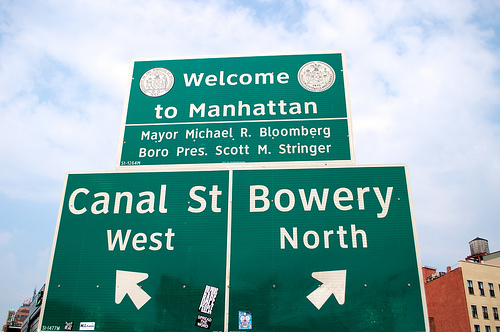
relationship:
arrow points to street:
[96, 262, 162, 314] [180, 170, 230, 219]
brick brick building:
[425, 265, 470, 331] [417, 233, 497, 330]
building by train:
[417, 233, 497, 330] [19, 285, 48, 331]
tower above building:
[457, 233, 495, 260] [417, 233, 497, 330]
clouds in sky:
[15, 24, 131, 84] [0, 2, 500, 271]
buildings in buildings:
[3, 280, 43, 331] [3, 284, 43, 331]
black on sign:
[195, 282, 219, 328] [47, 163, 219, 323]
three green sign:
[11, 51, 446, 330] [225, 157, 440, 325]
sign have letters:
[225, 157, 440, 325] [166, 68, 293, 89]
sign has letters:
[118, 49, 360, 164] [166, 68, 293, 89]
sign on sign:
[225, 157, 440, 325] [225, 157, 440, 325]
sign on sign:
[47, 163, 219, 323] [47, 163, 229, 332]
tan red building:
[460, 248, 499, 331] [417, 233, 497, 330]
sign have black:
[225, 157, 440, 325] [195, 282, 219, 328]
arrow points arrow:
[96, 262, 162, 314] [111, 268, 153, 309]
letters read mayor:
[138, 126, 182, 142] [134, 126, 183, 146]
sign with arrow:
[47, 163, 219, 323] [302, 269, 349, 311]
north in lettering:
[274, 219, 375, 255] [279, 224, 372, 253]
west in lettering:
[102, 222, 177, 256] [106, 223, 180, 253]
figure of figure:
[239, 310, 253, 329] [236, 308, 261, 329]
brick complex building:
[422, 267, 481, 331] [417, 233, 497, 330]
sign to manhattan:
[118, 49, 360, 164] [185, 99, 321, 118]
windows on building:
[465, 272, 500, 302] [417, 233, 497, 330]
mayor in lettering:
[134, 126, 183, 146] [138, 128, 180, 144]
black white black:
[195, 280, 217, 313] [195, 282, 219, 328]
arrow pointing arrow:
[96, 262, 162, 314] [111, 268, 153, 309]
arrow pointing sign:
[303, 264, 353, 314] [225, 157, 440, 325]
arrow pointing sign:
[96, 262, 162, 314] [47, 163, 229, 332]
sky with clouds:
[0, 2, 500, 271] [15, 24, 131, 84]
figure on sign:
[239, 310, 253, 329] [47, 163, 219, 323]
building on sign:
[417, 233, 497, 330] [225, 157, 440, 325]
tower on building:
[457, 233, 495, 260] [417, 233, 497, 330]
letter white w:
[180, 68, 205, 87] [180, 69, 205, 88]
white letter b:
[257, 126, 269, 139] [140, 148, 146, 158]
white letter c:
[225, 71, 241, 89] [226, 71, 238, 87]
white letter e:
[208, 105, 220, 117] [205, 73, 217, 87]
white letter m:
[208, 105, 220, 117] [185, 101, 207, 119]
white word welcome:
[208, 105, 220, 117] [179, 68, 290, 91]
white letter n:
[208, 105, 220, 117] [220, 102, 237, 119]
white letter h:
[208, 105, 220, 117] [236, 97, 253, 114]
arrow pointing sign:
[96, 262, 162, 314] [225, 157, 440, 325]